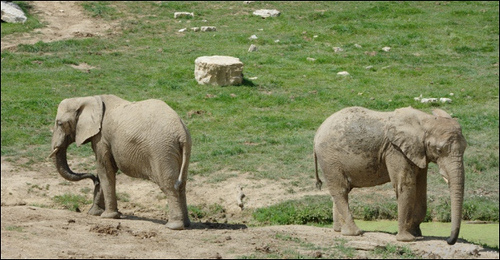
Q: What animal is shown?
A: Elephants.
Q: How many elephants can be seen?
A: 2.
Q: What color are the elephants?
A: Gray.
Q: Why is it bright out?
A: It's daytime.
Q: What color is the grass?
A: Green.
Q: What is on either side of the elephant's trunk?
A: Tusks.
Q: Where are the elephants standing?
A: On a rock.